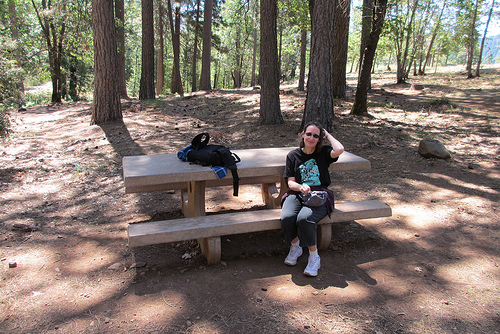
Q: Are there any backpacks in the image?
A: Yes, there is a backpack.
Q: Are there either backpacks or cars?
A: Yes, there is a backpack.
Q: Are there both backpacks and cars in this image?
A: No, there is a backpack but no cars.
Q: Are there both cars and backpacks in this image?
A: No, there is a backpack but no cars.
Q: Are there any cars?
A: No, there are no cars.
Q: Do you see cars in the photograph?
A: No, there are no cars.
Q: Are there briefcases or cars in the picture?
A: No, there are no cars or briefcases.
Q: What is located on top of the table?
A: The backpack is on top of the table.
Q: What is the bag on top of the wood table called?
A: The bag is a backpack.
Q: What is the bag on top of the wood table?
A: The bag is a backpack.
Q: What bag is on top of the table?
A: The bag is a backpack.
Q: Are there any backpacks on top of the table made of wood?
A: Yes, there is a backpack on top of the table.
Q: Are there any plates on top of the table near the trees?
A: No, there is a backpack on top of the table.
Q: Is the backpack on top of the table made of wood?
A: Yes, the backpack is on top of the table.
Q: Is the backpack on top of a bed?
A: No, the backpack is on top of the table.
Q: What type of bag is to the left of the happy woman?
A: The bag is a backpack.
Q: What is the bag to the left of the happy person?
A: The bag is a backpack.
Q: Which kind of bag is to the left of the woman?
A: The bag is a backpack.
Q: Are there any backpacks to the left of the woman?
A: Yes, there is a backpack to the left of the woman.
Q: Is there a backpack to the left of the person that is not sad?
A: Yes, there is a backpack to the left of the woman.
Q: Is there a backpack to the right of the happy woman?
A: No, the backpack is to the left of the woman.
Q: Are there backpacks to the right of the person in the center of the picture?
A: No, the backpack is to the left of the woman.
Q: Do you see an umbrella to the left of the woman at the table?
A: No, there is a backpack to the left of the woman.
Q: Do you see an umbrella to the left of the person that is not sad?
A: No, there is a backpack to the left of the woman.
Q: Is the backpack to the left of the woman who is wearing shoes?
A: Yes, the backpack is to the left of the woman.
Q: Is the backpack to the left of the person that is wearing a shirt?
A: Yes, the backpack is to the left of the woman.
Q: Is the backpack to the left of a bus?
A: No, the backpack is to the left of the woman.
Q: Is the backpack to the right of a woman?
A: No, the backpack is to the left of a woman.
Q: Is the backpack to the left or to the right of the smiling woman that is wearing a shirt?
A: The backpack is to the left of the woman.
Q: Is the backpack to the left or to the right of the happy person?
A: The backpack is to the left of the woman.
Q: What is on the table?
A: The backpack is on the table.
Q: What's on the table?
A: The backpack is on the table.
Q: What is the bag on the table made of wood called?
A: The bag is a backpack.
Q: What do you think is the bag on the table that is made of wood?
A: The bag is a backpack.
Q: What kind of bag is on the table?
A: The bag is a backpack.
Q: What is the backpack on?
A: The backpack is on the table.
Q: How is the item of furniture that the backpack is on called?
A: The piece of furniture is a table.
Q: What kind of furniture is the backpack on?
A: The backpack is on the table.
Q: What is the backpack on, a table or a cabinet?
A: The backpack is on a table.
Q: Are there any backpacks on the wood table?
A: Yes, there is a backpack on the table.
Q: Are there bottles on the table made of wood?
A: No, there is a backpack on the table.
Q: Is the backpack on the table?
A: Yes, the backpack is on the table.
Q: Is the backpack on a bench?
A: No, the backpack is on the table.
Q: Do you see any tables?
A: Yes, there is a table.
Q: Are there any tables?
A: Yes, there is a table.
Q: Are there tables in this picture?
A: Yes, there is a table.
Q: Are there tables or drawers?
A: Yes, there is a table.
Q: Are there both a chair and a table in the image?
A: No, there is a table but no chairs.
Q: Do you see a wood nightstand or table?
A: Yes, there is a wood table.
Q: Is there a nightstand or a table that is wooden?
A: Yes, the table is wooden.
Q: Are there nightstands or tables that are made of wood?
A: Yes, the table is made of wood.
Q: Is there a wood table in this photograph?
A: Yes, there is a wood table.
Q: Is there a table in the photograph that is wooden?
A: Yes, there is a table that is wooden.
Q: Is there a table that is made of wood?
A: Yes, there is a table that is made of wood.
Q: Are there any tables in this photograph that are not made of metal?
A: Yes, there is a table that is made of wood.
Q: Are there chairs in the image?
A: No, there are no chairs.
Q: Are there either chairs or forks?
A: No, there are no chairs or forks.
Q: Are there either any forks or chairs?
A: No, there are no chairs or forks.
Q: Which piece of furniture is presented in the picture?
A: The piece of furniture is a table.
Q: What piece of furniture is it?
A: The piece of furniture is a table.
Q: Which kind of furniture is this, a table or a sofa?
A: This is a table.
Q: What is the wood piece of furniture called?
A: The piece of furniture is a table.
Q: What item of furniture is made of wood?
A: The piece of furniture is a table.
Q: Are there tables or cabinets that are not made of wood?
A: No, there is a table but it is made of wood.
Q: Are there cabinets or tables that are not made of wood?
A: No, there is a table but it is made of wood.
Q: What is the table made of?
A: The table is made of wood.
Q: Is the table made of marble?
A: No, the table is made of wood.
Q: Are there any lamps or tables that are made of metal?
A: No, there is a table but it is made of wood.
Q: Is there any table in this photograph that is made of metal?
A: No, there is a table but it is made of wood.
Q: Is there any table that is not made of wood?
A: No, there is a table but it is made of wood.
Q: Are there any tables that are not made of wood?
A: No, there is a table but it is made of wood.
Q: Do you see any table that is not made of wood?
A: No, there is a table but it is made of wood.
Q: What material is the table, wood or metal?
A: The table is made of wood.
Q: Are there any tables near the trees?
A: Yes, there is a table near the trees.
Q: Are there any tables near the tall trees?
A: Yes, there is a table near the trees.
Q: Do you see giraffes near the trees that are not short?
A: No, there is a table near the trees.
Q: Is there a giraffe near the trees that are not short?
A: No, there is a table near the trees.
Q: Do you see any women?
A: Yes, there is a woman.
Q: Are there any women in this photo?
A: Yes, there is a woman.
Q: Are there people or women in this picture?
A: Yes, there is a woman.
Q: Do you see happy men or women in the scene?
A: Yes, there is a happy woman.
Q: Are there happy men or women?
A: Yes, there is a happy woman.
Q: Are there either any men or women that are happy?
A: Yes, the woman is happy.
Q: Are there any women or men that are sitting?
A: Yes, the woman is sitting.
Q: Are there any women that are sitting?
A: Yes, there is a woman that is sitting.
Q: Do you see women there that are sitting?
A: Yes, there is a woman that is sitting.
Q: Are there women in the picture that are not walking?
A: Yes, there is a woman that is sitting.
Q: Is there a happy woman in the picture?
A: Yes, there is a happy woman.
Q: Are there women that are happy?
A: Yes, there is a woman that is happy.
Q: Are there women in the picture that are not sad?
A: Yes, there is a happy woman.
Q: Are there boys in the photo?
A: No, there are no boys.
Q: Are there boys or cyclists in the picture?
A: No, there are no boys or cyclists.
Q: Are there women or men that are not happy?
A: No, there is a woman but she is happy.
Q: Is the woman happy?
A: Yes, the woman is happy.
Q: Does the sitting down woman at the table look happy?
A: Yes, the woman is happy.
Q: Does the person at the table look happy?
A: Yes, the woman is happy.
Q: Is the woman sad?
A: No, the woman is happy.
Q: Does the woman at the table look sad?
A: No, the woman is happy.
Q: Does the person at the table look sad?
A: No, the woman is happy.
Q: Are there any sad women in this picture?
A: No, there is a woman but she is happy.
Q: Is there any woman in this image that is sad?
A: No, there is a woman but she is happy.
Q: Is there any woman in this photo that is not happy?
A: No, there is a woman but she is happy.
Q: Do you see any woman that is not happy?
A: No, there is a woman but she is happy.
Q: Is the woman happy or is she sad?
A: The woman is happy.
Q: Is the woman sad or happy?
A: The woman is happy.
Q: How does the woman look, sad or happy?
A: The woman is happy.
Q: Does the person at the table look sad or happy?
A: The woman is happy.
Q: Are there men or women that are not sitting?
A: No, there is a woman but she is sitting.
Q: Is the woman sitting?
A: Yes, the woman is sitting.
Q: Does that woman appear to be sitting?
A: Yes, the woman is sitting.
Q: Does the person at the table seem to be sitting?
A: Yes, the woman is sitting.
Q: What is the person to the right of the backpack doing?
A: The woman is sitting.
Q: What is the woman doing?
A: The woman is sitting.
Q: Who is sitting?
A: The woman is sitting.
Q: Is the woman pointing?
A: No, the woman is sitting.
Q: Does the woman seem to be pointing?
A: No, the woman is sitting.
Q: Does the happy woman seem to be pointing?
A: No, the woman is sitting.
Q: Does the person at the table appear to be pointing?
A: No, the woman is sitting.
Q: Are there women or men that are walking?
A: No, there is a woman but she is sitting.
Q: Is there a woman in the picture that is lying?
A: No, there is a woman but she is sitting.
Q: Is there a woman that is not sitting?
A: No, there is a woman but she is sitting.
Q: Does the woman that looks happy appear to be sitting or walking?
A: The woman is sitting.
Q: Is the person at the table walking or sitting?
A: The woman is sitting.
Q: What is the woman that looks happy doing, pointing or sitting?
A: The woman is sitting.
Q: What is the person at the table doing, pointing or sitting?
A: The woman is sitting.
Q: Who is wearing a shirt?
A: The woman is wearing a shirt.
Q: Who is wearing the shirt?
A: The woman is wearing a shirt.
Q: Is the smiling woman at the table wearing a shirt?
A: Yes, the woman is wearing a shirt.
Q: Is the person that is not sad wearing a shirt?
A: Yes, the woman is wearing a shirt.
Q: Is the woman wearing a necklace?
A: No, the woman is wearing a shirt.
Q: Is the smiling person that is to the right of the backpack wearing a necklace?
A: No, the woman is wearing a shirt.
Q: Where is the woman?
A: The woman is at the table.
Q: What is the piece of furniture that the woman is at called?
A: The piece of furniture is a table.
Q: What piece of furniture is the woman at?
A: The woman is at the table.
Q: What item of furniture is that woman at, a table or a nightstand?
A: The woman is at a table.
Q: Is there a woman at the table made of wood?
A: Yes, there is a woman at the table.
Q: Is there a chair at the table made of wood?
A: No, there is a woman at the table.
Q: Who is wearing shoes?
A: The woman is wearing shoes.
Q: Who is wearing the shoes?
A: The woman is wearing shoes.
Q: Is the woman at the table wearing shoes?
A: Yes, the woman is wearing shoes.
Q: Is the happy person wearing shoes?
A: Yes, the woman is wearing shoes.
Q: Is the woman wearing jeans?
A: No, the woman is wearing shoes.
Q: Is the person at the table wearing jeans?
A: No, the woman is wearing shoes.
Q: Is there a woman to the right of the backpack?
A: Yes, there is a woman to the right of the backpack.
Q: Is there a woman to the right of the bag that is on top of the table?
A: Yes, there is a woman to the right of the backpack.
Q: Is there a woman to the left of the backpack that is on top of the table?
A: No, the woman is to the right of the backpack.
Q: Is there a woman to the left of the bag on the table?
A: No, the woman is to the right of the backpack.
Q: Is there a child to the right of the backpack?
A: No, there is a woman to the right of the backpack.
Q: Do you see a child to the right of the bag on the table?
A: No, there is a woman to the right of the backpack.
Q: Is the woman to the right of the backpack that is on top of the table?
A: Yes, the woman is to the right of the backpack.